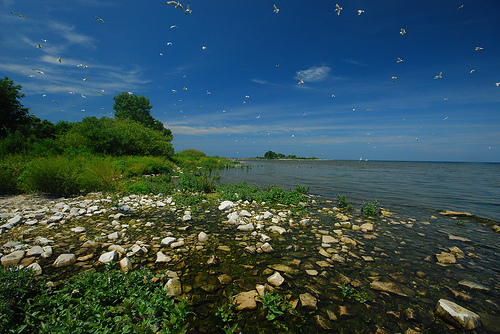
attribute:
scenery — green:
[8, 88, 355, 332]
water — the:
[212, 153, 499, 330]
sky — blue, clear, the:
[5, 3, 495, 167]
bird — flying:
[332, 3, 344, 15]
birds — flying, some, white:
[331, 3, 444, 86]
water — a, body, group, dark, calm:
[0, 159, 499, 333]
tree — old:
[112, 91, 173, 134]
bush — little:
[22, 154, 98, 198]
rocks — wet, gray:
[1, 195, 498, 333]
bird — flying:
[272, 3, 280, 13]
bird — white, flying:
[357, 8, 365, 15]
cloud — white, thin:
[292, 60, 331, 86]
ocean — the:
[239, 161, 499, 217]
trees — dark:
[0, 76, 174, 155]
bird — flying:
[400, 28, 407, 35]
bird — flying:
[396, 57, 403, 65]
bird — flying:
[433, 70, 443, 80]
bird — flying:
[473, 46, 483, 53]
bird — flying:
[389, 75, 399, 84]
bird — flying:
[167, 0, 189, 15]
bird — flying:
[96, 15, 106, 25]